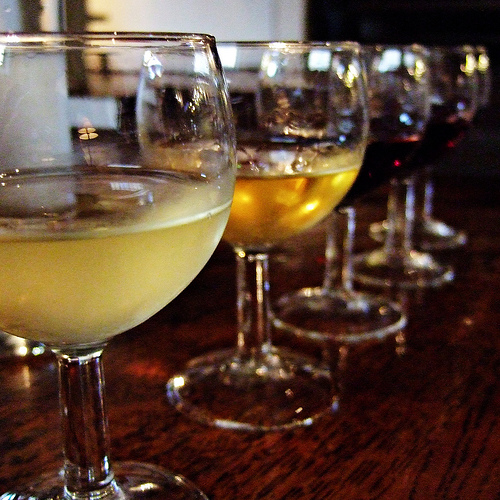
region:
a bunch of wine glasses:
[12, 23, 472, 418]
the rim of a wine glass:
[40, 28, 90, 65]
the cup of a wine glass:
[28, 75, 210, 315]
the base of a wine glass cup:
[30, 293, 145, 358]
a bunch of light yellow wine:
[37, 148, 185, 320]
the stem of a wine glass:
[52, 359, 116, 497]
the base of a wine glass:
[11, 473, 192, 498]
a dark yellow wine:
[240, 178, 321, 233]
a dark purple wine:
[357, 121, 429, 183]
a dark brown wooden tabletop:
[357, 396, 459, 491]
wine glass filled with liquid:
[0, 45, 213, 355]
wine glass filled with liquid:
[171, 61, 352, 236]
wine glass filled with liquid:
[323, 45, 411, 221]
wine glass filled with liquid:
[405, 53, 469, 176]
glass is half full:
[0, 100, 201, 362]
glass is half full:
[201, 60, 363, 338]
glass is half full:
[302, 57, 411, 309]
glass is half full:
[424, 49, 461, 209]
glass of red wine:
[331, 69, 395, 336]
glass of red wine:
[420, 58, 470, 244]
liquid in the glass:
[15, 255, 122, 272]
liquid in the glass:
[220, 173, 317, 212]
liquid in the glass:
[386, 121, 416, 163]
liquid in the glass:
[428, 111, 463, 131]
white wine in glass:
[110, 253, 181, 285]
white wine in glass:
[257, 195, 294, 220]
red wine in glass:
[375, 136, 420, 169]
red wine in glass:
[448, 100, 473, 132]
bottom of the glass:
[236, 373, 338, 422]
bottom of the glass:
[312, 294, 374, 329]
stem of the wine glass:
[49, 359, 125, 481]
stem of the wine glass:
[237, 255, 270, 362]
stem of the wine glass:
[320, 207, 358, 302]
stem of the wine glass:
[390, 184, 415, 260]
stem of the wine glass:
[406, 177, 436, 224]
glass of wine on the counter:
[370, 40, 439, 294]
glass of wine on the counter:
[250, 31, 335, 413]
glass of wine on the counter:
[432, 37, 480, 244]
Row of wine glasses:
[0, 25, 494, 496]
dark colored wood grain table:
[2, 172, 498, 498]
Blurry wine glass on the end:
[368, 36, 479, 252]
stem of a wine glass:
[228, 238, 280, 381]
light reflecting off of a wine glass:
[219, 34, 369, 86]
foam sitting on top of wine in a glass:
[0, 171, 233, 241]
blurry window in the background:
[64, 2, 311, 92]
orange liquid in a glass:
[145, 144, 367, 253]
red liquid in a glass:
[336, 119, 422, 214]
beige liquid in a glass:
[1, 171, 236, 356]